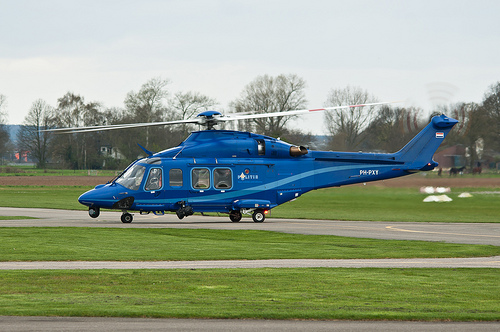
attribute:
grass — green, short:
[0, 266, 499, 319]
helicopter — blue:
[30, 99, 461, 222]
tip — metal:
[77, 182, 124, 210]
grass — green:
[2, 226, 499, 263]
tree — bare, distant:
[322, 85, 382, 153]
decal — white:
[237, 168, 261, 183]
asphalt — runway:
[3, 206, 498, 246]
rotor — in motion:
[405, 77, 475, 149]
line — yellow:
[383, 223, 499, 239]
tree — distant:
[238, 72, 305, 139]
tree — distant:
[15, 98, 65, 170]